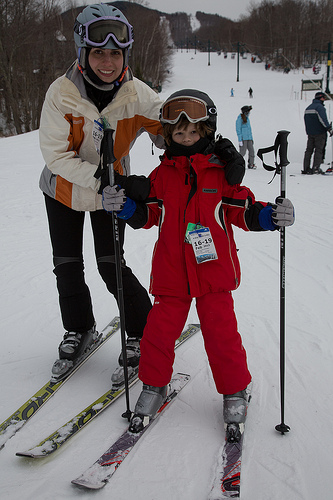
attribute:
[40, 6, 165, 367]
instructor — skiing, smiling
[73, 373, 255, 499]
skis — grey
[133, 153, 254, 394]
snowsuit — red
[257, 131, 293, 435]
pole — black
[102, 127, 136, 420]
pole — black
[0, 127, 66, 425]
snow — white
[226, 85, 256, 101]
people — skiing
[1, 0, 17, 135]
tree — leafless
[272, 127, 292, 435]
stick — black